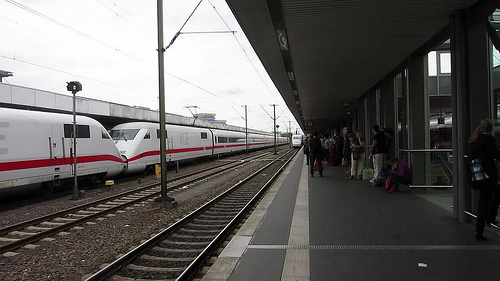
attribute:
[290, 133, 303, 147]
train — stopped, white, coming this way, red striped, passenger train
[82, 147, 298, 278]
tracks — oiled, long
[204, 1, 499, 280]
train station — here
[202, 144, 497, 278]
boarding platform — grey, sheltered, paved, here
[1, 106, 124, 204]
train — passenger train, electric, striped, white, facing away, red, grey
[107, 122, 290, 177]
train — striped, white, sleek, for passengers, grey, red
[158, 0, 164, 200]
pole — grey, metal, tall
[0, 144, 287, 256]
tracks — here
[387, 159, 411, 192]
person — waiting, seated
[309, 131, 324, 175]
person — waiting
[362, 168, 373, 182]
travel bag — green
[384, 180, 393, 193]
travel bag — red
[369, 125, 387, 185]
passenger — waiting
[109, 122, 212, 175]
train engine — white, red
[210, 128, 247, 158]
train car — white, red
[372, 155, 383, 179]
pants — white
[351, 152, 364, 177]
pants — white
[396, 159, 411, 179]
shirt — pink